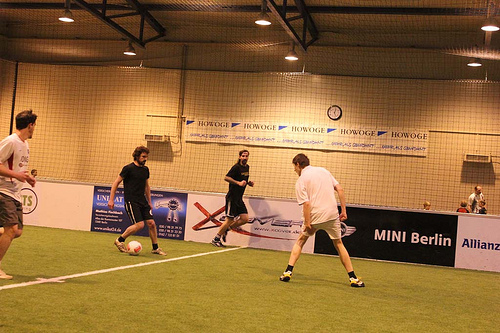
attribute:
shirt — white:
[295, 165, 340, 226]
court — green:
[0, 225, 499, 332]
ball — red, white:
[127, 240, 142, 256]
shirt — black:
[118, 161, 150, 202]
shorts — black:
[123, 200, 153, 224]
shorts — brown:
[0, 193, 24, 226]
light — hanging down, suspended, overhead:
[123, 43, 137, 57]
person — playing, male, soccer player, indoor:
[280, 153, 365, 286]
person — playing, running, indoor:
[106, 146, 166, 256]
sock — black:
[348, 269, 358, 279]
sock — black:
[285, 264, 295, 272]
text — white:
[373, 228, 452, 247]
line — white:
[0, 245, 248, 291]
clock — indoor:
[326, 105, 343, 121]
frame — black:
[326, 105, 343, 120]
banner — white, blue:
[180, 115, 431, 156]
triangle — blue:
[186, 119, 196, 125]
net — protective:
[1, 0, 498, 214]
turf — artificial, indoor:
[1, 223, 499, 332]